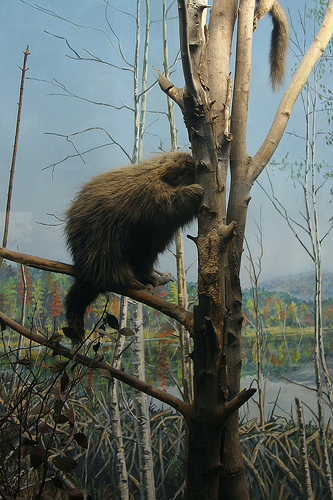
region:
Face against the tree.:
[147, 149, 208, 183]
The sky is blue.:
[10, 11, 88, 49]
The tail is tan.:
[265, 18, 297, 57]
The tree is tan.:
[206, 4, 260, 41]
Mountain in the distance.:
[279, 267, 332, 297]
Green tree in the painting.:
[239, 293, 262, 334]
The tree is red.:
[2, 272, 43, 305]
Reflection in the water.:
[243, 342, 302, 366]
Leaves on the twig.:
[33, 373, 81, 417]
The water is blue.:
[259, 372, 318, 407]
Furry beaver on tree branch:
[67, 113, 233, 291]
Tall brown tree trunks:
[160, 7, 267, 496]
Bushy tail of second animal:
[265, 13, 291, 91]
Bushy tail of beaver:
[46, 285, 100, 345]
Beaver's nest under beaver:
[28, 394, 329, 499]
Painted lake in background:
[35, 332, 330, 415]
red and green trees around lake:
[2, 261, 326, 331]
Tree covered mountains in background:
[250, 258, 329, 307]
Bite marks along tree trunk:
[196, 243, 215, 262]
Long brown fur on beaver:
[53, 158, 187, 273]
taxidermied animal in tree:
[42, 145, 193, 326]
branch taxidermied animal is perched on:
[5, 238, 188, 321]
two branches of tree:
[3, 241, 188, 415]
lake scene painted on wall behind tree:
[9, 24, 321, 483]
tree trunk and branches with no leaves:
[9, 7, 306, 466]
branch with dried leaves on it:
[20, 293, 131, 489]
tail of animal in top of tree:
[256, 8, 297, 81]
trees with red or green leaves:
[9, 263, 297, 335]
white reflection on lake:
[78, 370, 332, 431]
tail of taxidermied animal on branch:
[51, 281, 103, 338]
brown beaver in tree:
[65, 143, 214, 321]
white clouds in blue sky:
[5, 8, 43, 45]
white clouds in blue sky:
[264, 226, 288, 261]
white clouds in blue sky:
[11, 217, 33, 240]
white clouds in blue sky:
[21, 218, 42, 248]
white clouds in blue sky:
[249, 200, 268, 221]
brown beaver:
[61, 139, 200, 282]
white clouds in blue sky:
[254, 93, 267, 108]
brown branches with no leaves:
[161, 18, 253, 98]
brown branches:
[104, 412, 169, 460]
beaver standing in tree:
[58, 157, 194, 335]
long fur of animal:
[54, 153, 206, 295]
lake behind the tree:
[29, 329, 322, 421]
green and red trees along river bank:
[6, 260, 319, 320]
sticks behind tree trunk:
[2, 347, 322, 492]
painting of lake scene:
[6, 9, 316, 486]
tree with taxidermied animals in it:
[6, 6, 303, 491]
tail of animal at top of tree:
[263, 4, 290, 80]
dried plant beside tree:
[0, 307, 140, 486]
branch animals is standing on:
[8, 243, 188, 322]